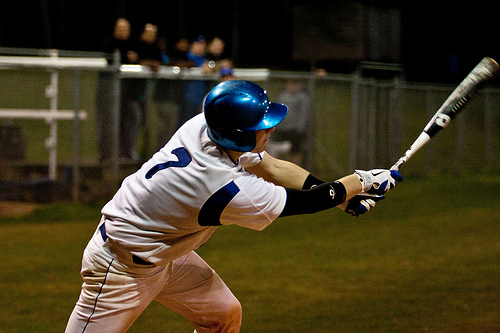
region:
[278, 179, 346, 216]
a long black armband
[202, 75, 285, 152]
a blue helmet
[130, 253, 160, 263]
part of a black belt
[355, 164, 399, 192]
a man's blue and white glove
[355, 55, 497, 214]
a long black and white baseball bat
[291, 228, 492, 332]
a section of green grass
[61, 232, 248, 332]
part of a man's pants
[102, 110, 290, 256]
a man's uniform shirt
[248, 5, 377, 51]
part of a black sky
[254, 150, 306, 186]
the arm of a man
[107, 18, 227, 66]
Fans leaning on the fence watching the ball game.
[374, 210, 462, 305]
Bright green grass on the ball field.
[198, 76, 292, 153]
Bright blue batting helmet.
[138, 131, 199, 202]
Blue number seven on the shirt.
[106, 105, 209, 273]
White shirt with a blue number.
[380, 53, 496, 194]
Black baseball bat in motion.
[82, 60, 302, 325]
The player is having fun.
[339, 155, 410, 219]
Player wearing blue and white gloves.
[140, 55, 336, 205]
Batter hopes he can hit the ball.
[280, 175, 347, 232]
Black sleeves under the jersey.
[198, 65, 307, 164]
batting helmet is blue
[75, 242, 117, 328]
blue stripe on pants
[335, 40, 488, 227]
swinging the bat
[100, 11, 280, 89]
fans watching the game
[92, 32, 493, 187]
fence along the baseball field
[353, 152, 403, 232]
batter is wearing batting gloves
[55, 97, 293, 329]
uniforms are blue and white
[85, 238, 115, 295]
grass stain on the pants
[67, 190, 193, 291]
blue belt on the pants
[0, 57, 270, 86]
fence bar is white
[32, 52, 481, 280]
the man is playing baseball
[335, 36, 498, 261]
the man is holding a bat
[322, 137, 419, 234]
the man is wearing gloves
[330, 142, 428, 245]
the gloves are white and blue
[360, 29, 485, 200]
the bat is black and white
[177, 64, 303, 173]
the player is wearing a helmet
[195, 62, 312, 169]
the helmet is blue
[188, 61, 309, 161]
the helmet is shiny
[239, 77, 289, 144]
the light is reflecting in the helmet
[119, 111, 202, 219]
the number 7 on the back of the shirt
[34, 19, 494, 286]
a baseball player at bat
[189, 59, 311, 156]
a blue baseball hat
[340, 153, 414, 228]
white gloves for the batter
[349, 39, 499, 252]
a black and white bat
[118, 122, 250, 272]
his team's colors are blue and white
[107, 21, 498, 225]
he is stepping into the hit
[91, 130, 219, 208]
the player's jersey number is 7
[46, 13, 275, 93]
spectators watching the event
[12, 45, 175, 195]
a gate on the field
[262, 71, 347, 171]
this person looks blurry in the shot